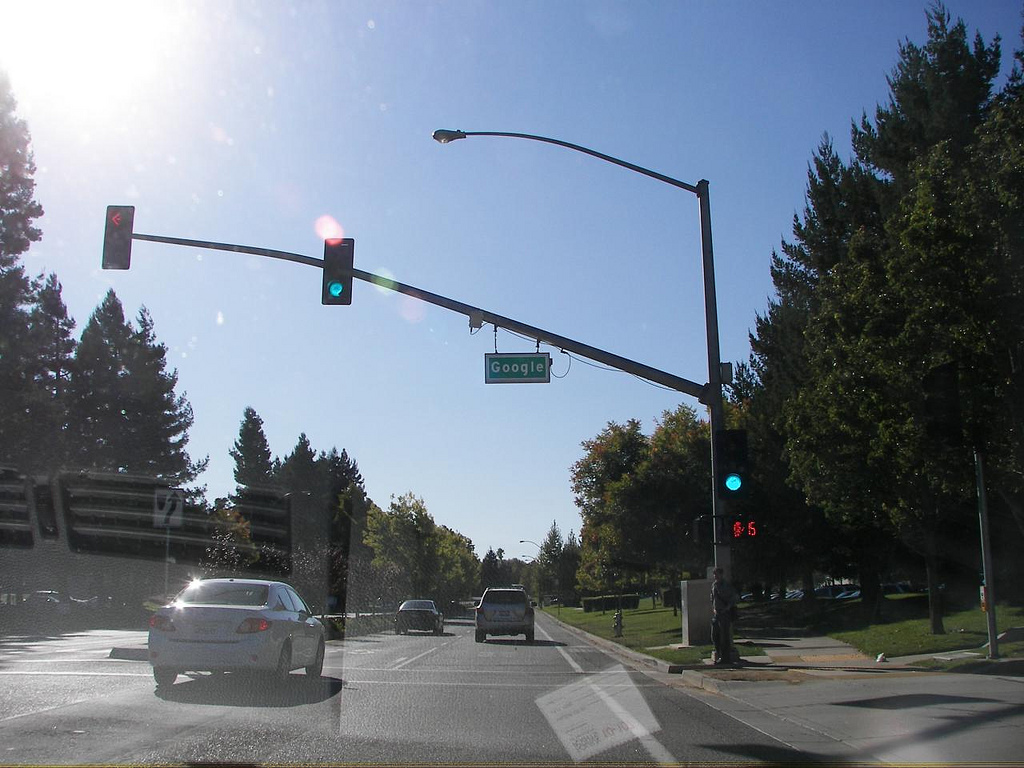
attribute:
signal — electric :
[320, 236, 356, 309]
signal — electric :
[100, 198, 140, 269]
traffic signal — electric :
[705, 415, 760, 517]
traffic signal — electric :
[316, 237, 359, 307]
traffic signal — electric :
[96, 199, 139, 275]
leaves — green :
[597, 431, 737, 565]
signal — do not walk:
[720, 520, 768, 549]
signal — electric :
[92, 200, 140, 270]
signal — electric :
[318, 232, 358, 306]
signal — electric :
[714, 421, 753, 498]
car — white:
[120, 469, 376, 738]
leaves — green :
[900, 146, 992, 235]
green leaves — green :
[841, 284, 928, 379]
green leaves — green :
[795, 362, 878, 481]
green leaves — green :
[628, 493, 667, 533]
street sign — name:
[473, 346, 597, 404]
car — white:
[130, 572, 336, 686]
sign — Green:
[471, 335, 561, 387]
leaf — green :
[955, 68, 968, 73]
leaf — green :
[884, 170, 910, 193]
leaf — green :
[933, 151, 954, 180]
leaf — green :
[905, 218, 929, 237]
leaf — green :
[821, 290, 841, 310]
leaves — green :
[851, 196, 1001, 431]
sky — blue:
[482, 172, 632, 294]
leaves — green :
[980, 129, 1020, 188]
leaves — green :
[833, 302, 896, 345]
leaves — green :
[970, 325, 1007, 383]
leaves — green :
[371, 521, 413, 565]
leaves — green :
[596, 441, 658, 487]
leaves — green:
[814, 235, 901, 325]